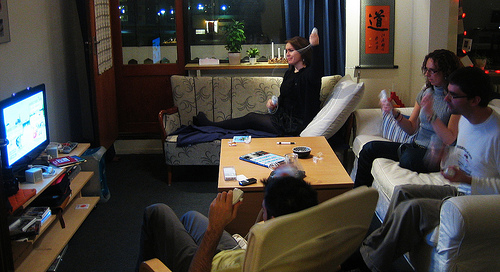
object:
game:
[1, 84, 52, 170]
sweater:
[276, 65, 324, 122]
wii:
[0, 90, 52, 169]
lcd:
[0, 81, 53, 174]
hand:
[378, 97, 394, 113]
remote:
[377, 88, 393, 113]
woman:
[352, 48, 467, 190]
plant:
[245, 45, 261, 64]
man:
[362, 63, 500, 272]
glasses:
[443, 85, 470, 99]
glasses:
[422, 64, 445, 74]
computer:
[0, 81, 53, 177]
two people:
[352, 46, 500, 272]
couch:
[346, 97, 500, 272]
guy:
[133, 156, 323, 272]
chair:
[137, 182, 382, 271]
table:
[215, 134, 357, 238]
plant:
[221, 17, 248, 65]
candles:
[270, 39, 275, 60]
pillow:
[381, 108, 420, 144]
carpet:
[53, 129, 218, 272]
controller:
[439, 146, 468, 179]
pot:
[248, 56, 256, 65]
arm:
[290, 44, 314, 70]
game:
[141, 22, 500, 271]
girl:
[189, 25, 328, 138]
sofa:
[156, 74, 355, 187]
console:
[0, 141, 105, 271]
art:
[352, 0, 401, 72]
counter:
[182, 60, 291, 77]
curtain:
[276, 0, 348, 78]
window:
[118, 0, 289, 66]